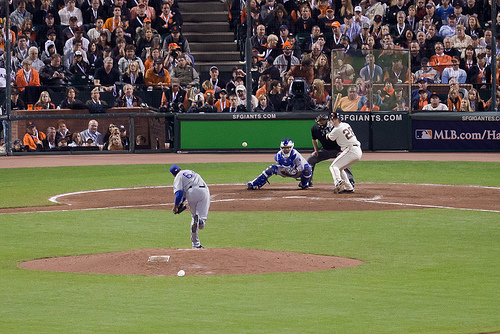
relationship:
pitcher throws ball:
[170, 164, 211, 249] [240, 141, 248, 148]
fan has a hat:
[40, 39, 60, 64] [43, 39, 58, 55]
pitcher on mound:
[170, 164, 211, 249] [17, 244, 367, 278]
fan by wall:
[40, 39, 60, 64] [12, 106, 167, 147]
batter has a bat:
[325, 110, 365, 195] [329, 91, 344, 123]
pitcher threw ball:
[170, 164, 211, 249] [240, 141, 248, 148]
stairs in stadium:
[176, 2, 247, 77] [1, 1, 499, 112]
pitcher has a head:
[170, 164, 211, 249] [171, 165, 183, 177]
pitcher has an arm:
[170, 164, 211, 249] [173, 179, 184, 213]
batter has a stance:
[325, 110, 365, 195] [329, 151, 364, 196]